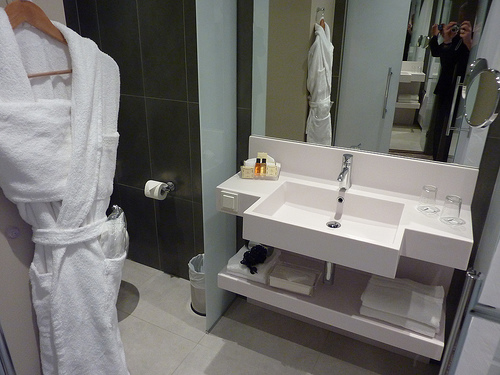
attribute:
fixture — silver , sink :
[329, 149, 360, 194]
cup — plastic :
[424, 186, 485, 238]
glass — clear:
[417, 180, 438, 225]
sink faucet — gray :
[334, 143, 361, 205]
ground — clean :
[296, 206, 392, 259]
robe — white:
[6, 29, 179, 366]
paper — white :
[141, 175, 177, 201]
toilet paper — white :
[142, 179, 168, 200]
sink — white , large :
[243, 152, 408, 277]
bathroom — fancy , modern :
[7, 15, 477, 352]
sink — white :
[246, 176, 412, 261]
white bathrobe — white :
[3, 10, 137, 374]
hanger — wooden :
[12, 2, 113, 81]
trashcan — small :
[178, 256, 220, 316]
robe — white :
[1, 77, 121, 372]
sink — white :
[216, 132, 477, 279]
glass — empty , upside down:
[416, 183, 437, 215]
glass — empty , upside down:
[440, 192, 462, 224]